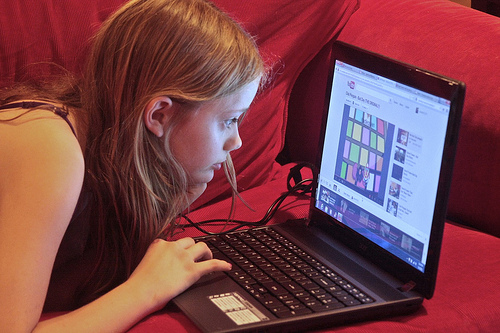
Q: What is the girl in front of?
A: Laptop.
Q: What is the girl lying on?
A: Couch.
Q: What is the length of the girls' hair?
A: Long.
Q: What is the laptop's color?
A: Black.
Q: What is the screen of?
A: Youtube video.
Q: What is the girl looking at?
A: A laptop screen.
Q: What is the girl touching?
A: A laptop.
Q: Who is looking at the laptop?
A: A girl.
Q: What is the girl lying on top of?
A: A couch.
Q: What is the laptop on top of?
A: A couch.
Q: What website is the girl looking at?
A: Youtube.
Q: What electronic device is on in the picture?
A: A laptop.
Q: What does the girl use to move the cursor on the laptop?
A: The touchpad.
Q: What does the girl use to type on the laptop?
A: The keyboard.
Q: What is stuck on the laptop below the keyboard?
A: A sticker.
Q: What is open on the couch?
A: A computer.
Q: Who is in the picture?
A: A woman.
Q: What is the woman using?
A: A laptop.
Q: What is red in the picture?
A: A couch.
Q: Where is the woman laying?
A: A couch.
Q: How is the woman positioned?
A: Laying down.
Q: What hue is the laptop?
A: Black.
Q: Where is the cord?
A: On the couch.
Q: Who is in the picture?
A: A girl.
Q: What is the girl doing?
A: Using a computer.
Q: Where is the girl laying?
A: A couch.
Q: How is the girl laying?
A: Prone.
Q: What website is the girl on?
A: Youtube.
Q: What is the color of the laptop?
A: Black.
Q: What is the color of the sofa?
A: Red.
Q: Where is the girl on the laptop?
A: A couch.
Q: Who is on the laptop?
A: A girl.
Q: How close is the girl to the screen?
A: Within a foot.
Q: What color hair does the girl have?
A: Blonde.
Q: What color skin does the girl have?
A: White.